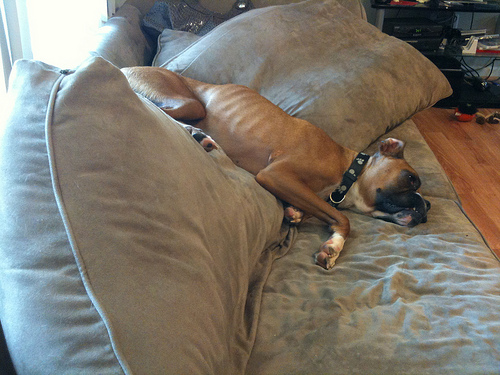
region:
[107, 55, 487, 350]
dog laying on the couch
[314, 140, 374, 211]
black collar around the neck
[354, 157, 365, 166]
design on the collar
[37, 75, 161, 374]
seam of the pillow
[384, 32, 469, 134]
corner of the pillow hanging over the edge of the couch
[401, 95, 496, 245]
light brown wooden floor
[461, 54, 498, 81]
bunch of black wires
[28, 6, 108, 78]
light shining through the window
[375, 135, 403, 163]
ear is curled over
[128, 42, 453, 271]
brown and black dog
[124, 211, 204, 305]
the couch is gray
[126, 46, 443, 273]
the dog is brown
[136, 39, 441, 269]
the dog is lying on a couch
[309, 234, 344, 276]
the dog has a paw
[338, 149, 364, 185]
the dog has a collar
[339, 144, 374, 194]
the collar is black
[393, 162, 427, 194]
the dog has an eye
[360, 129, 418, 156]
the dog has an ear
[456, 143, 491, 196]
the floor is brown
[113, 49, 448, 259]
the dog is skinny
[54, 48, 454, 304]
big dog with brown fur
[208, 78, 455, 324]
dog with black leather collar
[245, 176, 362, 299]
dog with white paw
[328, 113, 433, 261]
dog with big ear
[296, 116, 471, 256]
dog with big brown eye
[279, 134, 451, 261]
big dog with teeth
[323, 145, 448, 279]
dog with black moist nose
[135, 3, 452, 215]
big brown soft cushion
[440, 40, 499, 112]
several electrical wires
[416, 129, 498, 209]
brown wood floor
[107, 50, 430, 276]
a dog laying on the couch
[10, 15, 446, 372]
the big pillow of the couch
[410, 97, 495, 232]
the floor next to the couch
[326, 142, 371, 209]
the collar on the dog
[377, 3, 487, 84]
the entertainment system on the table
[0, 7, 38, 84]
the window next to the couch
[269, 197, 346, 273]
the paws of the dog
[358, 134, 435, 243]
the head of the dog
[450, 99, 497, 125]
the dog toys on the floor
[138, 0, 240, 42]
a purse sitting on the couch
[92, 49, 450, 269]
Boxer laying on the couch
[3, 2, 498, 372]
Overstuffed grey couch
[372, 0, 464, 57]
Black electricial components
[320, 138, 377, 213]
Black and silver collar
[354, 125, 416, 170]
Flopped up ear on boxer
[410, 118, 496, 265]
Hardwood floor that the couch is on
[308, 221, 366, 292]
Right paw of boxer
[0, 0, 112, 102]
Window behind the couch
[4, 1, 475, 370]
Large overstuffed cushion on the couch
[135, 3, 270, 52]
Blued denim item on the couch